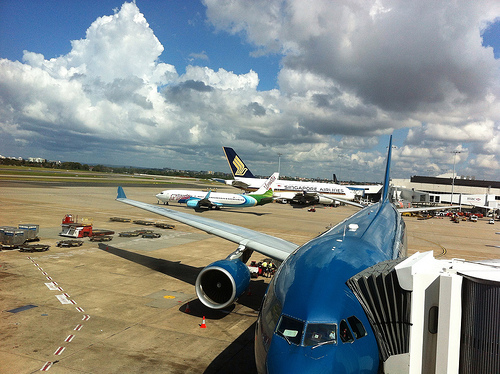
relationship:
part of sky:
[1, 2, 62, 45] [0, 0, 500, 184]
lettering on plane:
[282, 183, 344, 194] [208, 145, 363, 209]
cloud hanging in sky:
[0, 0, 499, 183] [0, 0, 500, 184]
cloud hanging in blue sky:
[0, 0, 499, 183] [153, 18, 300, 78]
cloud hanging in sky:
[0, 0, 499, 183] [5, 6, 52, 43]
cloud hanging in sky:
[149, 60, 179, 90] [5, 6, 52, 43]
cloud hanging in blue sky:
[0, 0, 499, 183] [3, 2, 68, 49]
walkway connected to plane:
[393, 189, 498, 274] [115, 131, 474, 372]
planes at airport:
[155, 182, 287, 215] [3, 159, 499, 372]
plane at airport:
[216, 145, 368, 210] [3, 159, 499, 372]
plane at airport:
[113, 134, 500, 373] [3, 159, 499, 372]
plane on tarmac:
[222, 160, 374, 207] [0, 183, 500, 373]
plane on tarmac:
[115, 131, 474, 372] [0, 183, 500, 373]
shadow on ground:
[85, 232, 280, 326] [200, 211, 333, 237]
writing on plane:
[282, 184, 343, 193] [222, 145, 358, 208]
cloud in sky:
[0, 0, 499, 183] [0, 0, 500, 184]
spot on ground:
[125, 277, 206, 332] [1, 163, 496, 370]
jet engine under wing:
[178, 240, 258, 311] [124, 184, 246, 230]